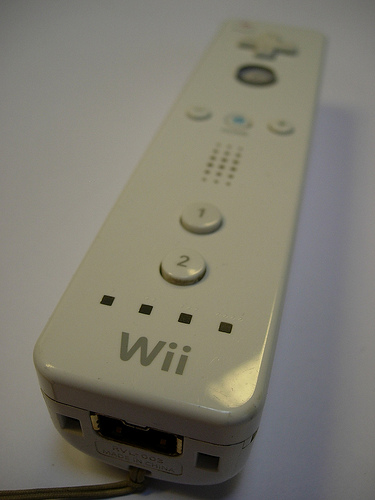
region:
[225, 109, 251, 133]
home button on a wii mote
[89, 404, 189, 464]
usb port on a wii mote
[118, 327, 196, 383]
grey wii logo on a wii mote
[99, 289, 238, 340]
dark power lights on a wii mote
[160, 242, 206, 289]
button with the number 2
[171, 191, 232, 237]
button with the number 1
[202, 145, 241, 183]
speaker on a wii mote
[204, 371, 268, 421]
light reflected on a wii mote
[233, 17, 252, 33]
power button on a wii mote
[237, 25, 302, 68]
directional button on a wii mote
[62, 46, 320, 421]
WHITE NINTENDO WII REMOTE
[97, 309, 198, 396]
SMALL WII LOGO ON BOTTOM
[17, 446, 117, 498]
STRAP ON WII CONTROLLER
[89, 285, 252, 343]
SMALL ROW OF LIGHTS ON REMOTE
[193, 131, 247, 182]
SMALL SPEAKER ON REMOTE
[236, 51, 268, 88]
LARGE CLEAR A BUTTON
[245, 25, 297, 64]
D PAD ON FAR END OF REMOTE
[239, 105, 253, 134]
SMALL HOME BUTTON ON REMOTE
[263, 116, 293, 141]
ROUND PLUS BUTTON ON REMOTE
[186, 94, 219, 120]
ROUND MINUS BUTTON ON REMOTE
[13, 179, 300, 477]
This is a wii remote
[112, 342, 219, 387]
This is a logo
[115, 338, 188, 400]
The logo says wii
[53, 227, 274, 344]
These are four lights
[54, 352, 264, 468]
This is a cable jack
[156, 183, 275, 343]
These are two buttons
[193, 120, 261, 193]
This is a vent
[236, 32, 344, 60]
This is a track pad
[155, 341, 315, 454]
The remote is plastic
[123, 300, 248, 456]
The remote is white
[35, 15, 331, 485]
white wii remote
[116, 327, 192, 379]
gray Wii symbol on remote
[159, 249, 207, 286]
white button with number 2 on it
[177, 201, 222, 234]
small white button with number 1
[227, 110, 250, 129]
small blue and white button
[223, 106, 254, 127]
blue and white home button on wii remote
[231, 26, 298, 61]
white arrow keys on wii remote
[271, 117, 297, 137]
small plus button on wii remote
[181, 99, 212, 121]
small minus white button on wii remote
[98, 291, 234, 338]
four little lights off in wii remote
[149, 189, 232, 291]
buttons on a controller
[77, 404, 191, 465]
a connection input of controller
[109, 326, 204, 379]
brand of the controller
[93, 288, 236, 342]
led signal lights of controller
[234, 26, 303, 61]
directional pad of controller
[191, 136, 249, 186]
speaker holes of controller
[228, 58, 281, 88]
button on controller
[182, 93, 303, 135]
buttons on the controller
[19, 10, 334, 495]
a wii controller